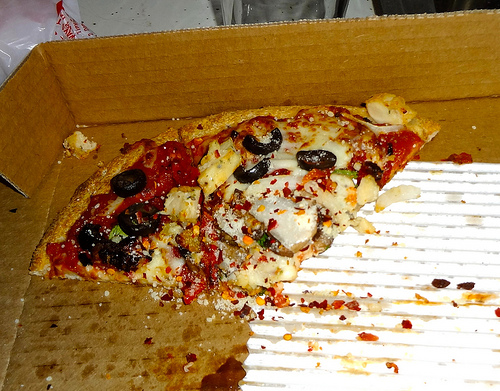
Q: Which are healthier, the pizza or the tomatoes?
A: The tomatoes are healthier than the pizza.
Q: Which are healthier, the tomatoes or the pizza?
A: The tomatoes are healthier than the pizza.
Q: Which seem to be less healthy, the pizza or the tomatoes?
A: The pizza are less healthy than the tomatoes.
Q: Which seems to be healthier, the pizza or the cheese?
A: The cheese is healthier than the pizza.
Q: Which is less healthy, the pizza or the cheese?
A: The pizza is less healthy than the cheese.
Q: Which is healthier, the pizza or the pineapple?
A: The pineapple is healthier than the pizza.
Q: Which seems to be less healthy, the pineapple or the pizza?
A: The pizza is less healthy than the pineapple.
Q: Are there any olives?
A: Yes, there are olives.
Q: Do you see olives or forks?
A: Yes, there are olives.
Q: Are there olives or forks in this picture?
A: Yes, there are olives.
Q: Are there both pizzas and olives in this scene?
A: Yes, there are both olives and a pizza.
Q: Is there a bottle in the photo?
A: No, there are no bottles.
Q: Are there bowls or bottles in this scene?
A: No, there are no bottles or bowls.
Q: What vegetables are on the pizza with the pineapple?
A: The vegetables are olives.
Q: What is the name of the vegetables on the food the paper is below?
A: The vegetables are olives.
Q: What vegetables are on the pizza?
A: The vegetables are olives.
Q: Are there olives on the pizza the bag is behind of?
A: Yes, there are olives on the pizza.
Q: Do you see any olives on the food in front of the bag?
A: Yes, there are olives on the pizza.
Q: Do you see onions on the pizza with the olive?
A: No, there are olives on the pizza.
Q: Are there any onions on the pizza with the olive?
A: No, there are olives on the pizza.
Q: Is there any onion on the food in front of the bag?
A: No, there are olives on the pizza.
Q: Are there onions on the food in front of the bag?
A: No, there are olives on the pizza.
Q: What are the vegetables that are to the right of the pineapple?
A: The vegetables are olives.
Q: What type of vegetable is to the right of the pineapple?
A: The vegetables are olives.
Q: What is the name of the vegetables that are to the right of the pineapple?
A: The vegetables are olives.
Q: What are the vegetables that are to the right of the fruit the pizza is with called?
A: The vegetables are olives.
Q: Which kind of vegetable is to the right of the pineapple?
A: The vegetables are olives.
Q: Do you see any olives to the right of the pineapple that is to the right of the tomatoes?
A: Yes, there are olives to the right of the pineapple.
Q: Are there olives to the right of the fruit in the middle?
A: Yes, there are olives to the right of the pineapple.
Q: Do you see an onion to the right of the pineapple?
A: No, there are olives to the right of the pineapple.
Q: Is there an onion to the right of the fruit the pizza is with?
A: No, there are olives to the right of the pineapple.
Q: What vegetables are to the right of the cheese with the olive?
A: The vegetables are olives.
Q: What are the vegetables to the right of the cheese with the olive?
A: The vegetables are olives.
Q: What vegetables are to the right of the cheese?
A: The vegetables are olives.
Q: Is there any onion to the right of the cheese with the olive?
A: No, there are olives to the right of the cheese.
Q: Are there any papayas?
A: No, there are no papayas.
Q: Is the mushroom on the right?
A: Yes, the mushroom is on the right of the image.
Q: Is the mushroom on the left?
A: No, the mushroom is on the right of the image.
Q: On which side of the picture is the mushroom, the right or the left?
A: The mushroom is on the right of the image.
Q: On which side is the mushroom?
A: The mushroom is on the right of the image.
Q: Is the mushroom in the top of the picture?
A: Yes, the mushroom is in the top of the image.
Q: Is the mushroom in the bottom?
A: No, the mushroom is in the top of the image.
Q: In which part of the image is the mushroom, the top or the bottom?
A: The mushroom is in the top of the image.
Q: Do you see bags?
A: Yes, there is a bag.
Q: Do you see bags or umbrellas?
A: Yes, there is a bag.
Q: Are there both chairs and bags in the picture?
A: No, there is a bag but no chairs.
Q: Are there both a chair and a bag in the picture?
A: No, there is a bag but no chairs.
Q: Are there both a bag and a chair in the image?
A: No, there is a bag but no chairs.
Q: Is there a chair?
A: No, there are no chairs.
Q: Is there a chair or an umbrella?
A: No, there are no chairs or umbrellas.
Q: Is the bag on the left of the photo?
A: Yes, the bag is on the left of the image.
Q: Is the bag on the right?
A: No, the bag is on the left of the image.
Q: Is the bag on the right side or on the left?
A: The bag is on the left of the image.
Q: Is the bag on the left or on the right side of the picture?
A: The bag is on the left of the image.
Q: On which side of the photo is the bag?
A: The bag is on the left of the image.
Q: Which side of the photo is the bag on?
A: The bag is on the left of the image.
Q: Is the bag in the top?
A: Yes, the bag is in the top of the image.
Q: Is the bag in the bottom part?
A: No, the bag is in the top of the image.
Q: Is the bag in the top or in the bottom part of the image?
A: The bag is in the top of the image.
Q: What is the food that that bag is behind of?
A: The food is a pizza.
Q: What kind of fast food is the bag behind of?
A: The bag is behind the pizza.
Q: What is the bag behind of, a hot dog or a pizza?
A: The bag is behind a pizza.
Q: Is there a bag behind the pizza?
A: Yes, there is a bag behind the pizza.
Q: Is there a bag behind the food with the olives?
A: Yes, there is a bag behind the pizza.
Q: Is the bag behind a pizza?
A: Yes, the bag is behind a pizza.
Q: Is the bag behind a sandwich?
A: No, the bag is behind a pizza.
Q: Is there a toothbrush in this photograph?
A: No, there are no toothbrushes.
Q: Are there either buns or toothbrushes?
A: No, there are no toothbrushes or buns.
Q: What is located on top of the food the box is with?
A: The toppings are on top of the pizza.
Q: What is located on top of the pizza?
A: The toppings are on top of the pizza.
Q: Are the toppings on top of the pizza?
A: Yes, the toppings are on top of the pizza.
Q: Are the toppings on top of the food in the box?
A: Yes, the toppings are on top of the pizza.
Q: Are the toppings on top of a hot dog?
A: No, the toppings are on top of the pizza.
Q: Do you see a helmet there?
A: No, there are no helmets.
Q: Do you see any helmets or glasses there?
A: No, there are no helmets or glasses.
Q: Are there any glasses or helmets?
A: No, there are no helmets or glasses.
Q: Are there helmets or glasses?
A: No, there are no helmets or glasses.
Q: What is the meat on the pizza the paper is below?
A: The meat is chicken.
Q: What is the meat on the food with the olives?
A: The meat is chicken.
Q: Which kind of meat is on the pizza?
A: The meat is chicken.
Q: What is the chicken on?
A: The chicken is on the pizza.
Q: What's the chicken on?
A: The chicken is on the pizza.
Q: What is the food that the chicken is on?
A: The food is a pizza.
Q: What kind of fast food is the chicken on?
A: The chicken is on the pizza.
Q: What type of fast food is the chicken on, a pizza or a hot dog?
A: The chicken is on a pizza.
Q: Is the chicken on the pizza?
A: Yes, the chicken is on the pizza.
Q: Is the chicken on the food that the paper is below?
A: Yes, the chicken is on the pizza.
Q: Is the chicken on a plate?
A: No, the chicken is on the pizza.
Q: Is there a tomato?
A: Yes, there are tomatoes.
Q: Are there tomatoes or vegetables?
A: Yes, there are tomatoes.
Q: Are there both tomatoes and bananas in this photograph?
A: No, there are tomatoes but no bananas.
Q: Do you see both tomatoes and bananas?
A: No, there are tomatoes but no bananas.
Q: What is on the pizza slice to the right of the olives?
A: The tomatoes are on the pizza slice.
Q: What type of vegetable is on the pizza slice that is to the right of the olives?
A: The vegetables are tomatoes.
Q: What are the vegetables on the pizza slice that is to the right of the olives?
A: The vegetables are tomatoes.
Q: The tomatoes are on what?
A: The tomatoes are on the pizza slice.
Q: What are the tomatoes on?
A: The tomatoes are on the pizza slice.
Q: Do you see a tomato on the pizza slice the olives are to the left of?
A: Yes, there are tomatoes on the pizza slice.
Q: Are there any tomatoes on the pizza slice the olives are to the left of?
A: Yes, there are tomatoes on the pizza slice.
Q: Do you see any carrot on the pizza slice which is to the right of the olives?
A: No, there are tomatoes on the pizza slice.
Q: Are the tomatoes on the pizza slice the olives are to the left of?
A: Yes, the tomatoes are on the pizza slice.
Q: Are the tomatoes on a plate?
A: No, the tomatoes are on the pizza slice.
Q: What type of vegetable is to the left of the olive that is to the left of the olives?
A: The vegetables are tomatoes.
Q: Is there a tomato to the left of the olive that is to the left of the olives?
A: Yes, there are tomatoes to the left of the olive.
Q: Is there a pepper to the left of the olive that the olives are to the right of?
A: No, there are tomatoes to the left of the olive.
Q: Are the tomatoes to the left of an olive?
A: Yes, the tomatoes are to the left of an olive.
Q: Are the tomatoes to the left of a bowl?
A: No, the tomatoes are to the left of an olive.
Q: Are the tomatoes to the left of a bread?
A: No, the tomatoes are to the left of an olive.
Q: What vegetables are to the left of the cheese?
A: The vegetables are tomatoes.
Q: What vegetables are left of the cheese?
A: The vegetables are tomatoes.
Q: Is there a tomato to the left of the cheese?
A: Yes, there are tomatoes to the left of the cheese.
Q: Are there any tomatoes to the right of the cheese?
A: No, the tomatoes are to the left of the cheese.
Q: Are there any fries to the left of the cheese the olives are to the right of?
A: No, there are tomatoes to the left of the cheese.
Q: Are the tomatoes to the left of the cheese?
A: Yes, the tomatoes are to the left of the cheese.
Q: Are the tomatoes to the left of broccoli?
A: No, the tomatoes are to the left of the cheese.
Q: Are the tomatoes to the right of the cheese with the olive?
A: No, the tomatoes are to the left of the cheese.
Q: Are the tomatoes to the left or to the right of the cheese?
A: The tomatoes are to the left of the cheese.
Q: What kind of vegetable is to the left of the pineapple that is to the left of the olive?
A: The vegetables are tomatoes.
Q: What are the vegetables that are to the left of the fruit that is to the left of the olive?
A: The vegetables are tomatoes.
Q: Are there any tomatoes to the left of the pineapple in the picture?
A: Yes, there are tomatoes to the left of the pineapple.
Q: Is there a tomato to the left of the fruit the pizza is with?
A: Yes, there are tomatoes to the left of the pineapple.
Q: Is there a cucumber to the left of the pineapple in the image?
A: No, there are tomatoes to the left of the pineapple.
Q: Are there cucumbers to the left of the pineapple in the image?
A: No, there are tomatoes to the left of the pineapple.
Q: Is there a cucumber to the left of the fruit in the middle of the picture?
A: No, there are tomatoes to the left of the pineapple.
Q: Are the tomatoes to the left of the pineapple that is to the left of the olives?
A: Yes, the tomatoes are to the left of the pineapple.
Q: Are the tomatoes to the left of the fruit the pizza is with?
A: Yes, the tomatoes are to the left of the pineapple.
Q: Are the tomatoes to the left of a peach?
A: No, the tomatoes are to the left of the pineapple.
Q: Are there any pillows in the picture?
A: No, there are no pillows.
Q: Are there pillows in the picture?
A: No, there are no pillows.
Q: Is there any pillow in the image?
A: No, there are no pillows.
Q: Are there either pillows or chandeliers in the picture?
A: No, there are no pillows or chandeliers.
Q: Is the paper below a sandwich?
A: No, the paper is below the pizza.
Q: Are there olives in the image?
A: Yes, there are olives.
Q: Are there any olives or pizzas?
A: Yes, there are olives.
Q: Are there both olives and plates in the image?
A: No, there are olives but no plates.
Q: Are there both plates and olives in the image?
A: No, there are olives but no plates.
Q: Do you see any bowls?
A: No, there are no bowls.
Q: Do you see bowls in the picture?
A: No, there are no bowls.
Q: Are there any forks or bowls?
A: No, there are no bowls or forks.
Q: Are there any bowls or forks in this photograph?
A: No, there are no bowls or forks.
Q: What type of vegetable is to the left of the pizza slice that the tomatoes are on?
A: The vegetables are olives.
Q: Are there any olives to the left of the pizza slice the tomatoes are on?
A: Yes, there are olives to the left of the pizza slice.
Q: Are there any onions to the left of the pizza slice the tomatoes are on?
A: No, there are olives to the left of the pizza slice.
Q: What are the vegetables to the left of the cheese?
A: The vegetables are olives.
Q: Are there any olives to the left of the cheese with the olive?
A: Yes, there are olives to the left of the cheese.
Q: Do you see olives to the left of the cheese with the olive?
A: Yes, there are olives to the left of the cheese.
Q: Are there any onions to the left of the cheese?
A: No, there are olives to the left of the cheese.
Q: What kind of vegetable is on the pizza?
A: The vegetables are olives.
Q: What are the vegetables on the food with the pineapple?
A: The vegetables are olives.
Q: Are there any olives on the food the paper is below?
A: Yes, there are olives on the pizza.